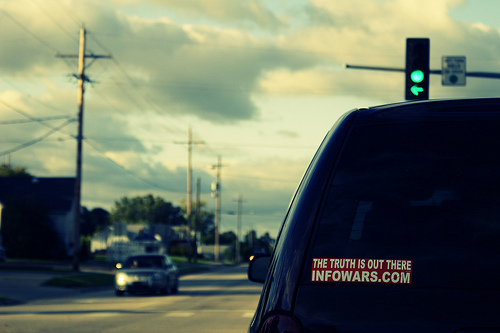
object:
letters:
[397, 271, 411, 283]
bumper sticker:
[310, 258, 412, 286]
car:
[245, 96, 498, 332]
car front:
[110, 253, 170, 295]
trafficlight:
[403, 37, 430, 102]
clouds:
[0, 0, 498, 240]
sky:
[0, 0, 499, 253]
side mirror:
[244, 248, 275, 284]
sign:
[440, 53, 467, 87]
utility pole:
[67, 27, 90, 272]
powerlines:
[0, 99, 215, 196]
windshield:
[127, 252, 168, 268]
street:
[0, 262, 270, 332]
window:
[297, 119, 499, 304]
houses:
[0, 176, 81, 263]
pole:
[345, 63, 499, 80]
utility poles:
[182, 127, 194, 230]